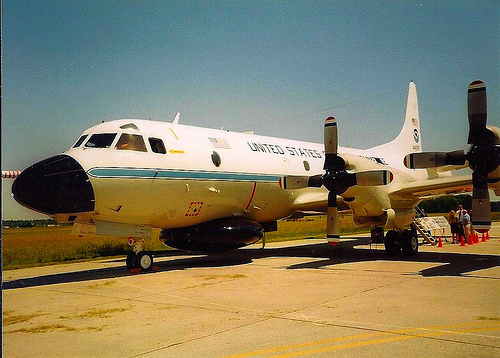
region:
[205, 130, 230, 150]
American flag on side of plane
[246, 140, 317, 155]
"United States" is written in blue and checked out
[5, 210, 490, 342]
yellow gray concrete tarmac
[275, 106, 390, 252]
beige propeller with red white and blue trim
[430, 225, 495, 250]
pile of orange cones near engine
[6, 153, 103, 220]
cone of plane appears dark, shiny and fast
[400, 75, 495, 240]
second propeller on second plane is taken care of by experts.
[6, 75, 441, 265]
white plane parked on runway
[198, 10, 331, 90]
this is the sky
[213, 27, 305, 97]
the sky is blue in color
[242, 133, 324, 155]
this is a writing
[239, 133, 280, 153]
the writing is black in color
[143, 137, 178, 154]
this is the window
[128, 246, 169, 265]
this is the wheel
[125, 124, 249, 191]
this is the body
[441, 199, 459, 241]
this is a lady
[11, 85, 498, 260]
Airplane on the tarmac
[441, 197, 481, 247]
People preparing to board the plane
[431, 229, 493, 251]
Safety cones on the tarmac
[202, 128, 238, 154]
American Flag on the side of the plane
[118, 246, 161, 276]
Wheel on a airplane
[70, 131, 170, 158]
Window on the front of the plane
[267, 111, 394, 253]
Rotors on a airplane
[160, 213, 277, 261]
black tube on the bottom of the plane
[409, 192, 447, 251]
Literature in front of the plane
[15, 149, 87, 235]
Black nose on a airplane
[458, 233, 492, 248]
Line of traffic cones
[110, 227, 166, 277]
An airplanes front wheels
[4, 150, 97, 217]
Black snout of an airplane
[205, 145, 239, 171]
Small round windows at the side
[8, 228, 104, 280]
Grasses beside the cement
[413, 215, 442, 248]
Small bridge at the back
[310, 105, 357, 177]
One of the blades in airplanes wing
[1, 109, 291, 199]
The airplane has blue line on its left side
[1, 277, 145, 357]
Stains on the floor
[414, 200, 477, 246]
People talking before the stairs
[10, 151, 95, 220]
the black nose of an airplane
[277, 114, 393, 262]
the propeller on an airplane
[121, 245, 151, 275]
the nose wheel on an airplane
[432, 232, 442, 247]
an orange cone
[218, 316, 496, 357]
a yellow line painted on the tarmac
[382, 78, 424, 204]
the tail of an airplane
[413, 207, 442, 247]
a staircase at an airplane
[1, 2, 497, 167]
a clear blue sky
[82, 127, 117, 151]
a window in the cockpit of an airplane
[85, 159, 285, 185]
a blue stripe on the side of an airplane